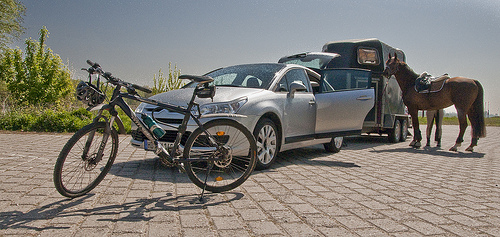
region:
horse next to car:
[380, 51, 487, 153]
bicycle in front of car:
[40, 59, 259, 197]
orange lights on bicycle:
[215, 126, 227, 183]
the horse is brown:
[381, 50, 489, 156]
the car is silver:
[126, 60, 383, 172]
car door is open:
[313, 63, 379, 136]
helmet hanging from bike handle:
[74, 57, 115, 110]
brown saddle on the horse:
[411, 69, 450, 95]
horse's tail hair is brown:
[471, 80, 488, 140]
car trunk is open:
[276, 50, 341, 78]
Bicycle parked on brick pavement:
[37, 57, 257, 199]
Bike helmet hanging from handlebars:
[73, 63, 105, 108]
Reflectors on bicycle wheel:
[210, 127, 227, 185]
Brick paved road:
[4, 124, 496, 235]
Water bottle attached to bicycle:
[138, 107, 164, 140]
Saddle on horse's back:
[412, 72, 449, 91]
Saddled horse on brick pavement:
[383, 51, 487, 155]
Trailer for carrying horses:
[322, 39, 409, 144]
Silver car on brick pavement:
[130, 47, 377, 165]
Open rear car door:
[311, 63, 377, 137]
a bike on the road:
[33, 43, 338, 235]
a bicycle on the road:
[46, 36, 286, 231]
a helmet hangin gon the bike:
[30, 28, 160, 170]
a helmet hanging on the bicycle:
[54, 57, 156, 173]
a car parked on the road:
[158, 6, 424, 228]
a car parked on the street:
[144, 4, 384, 232]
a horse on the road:
[367, 31, 496, 168]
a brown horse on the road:
[326, 29, 499, 213]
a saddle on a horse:
[373, 41, 489, 138]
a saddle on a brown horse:
[368, 26, 495, 157]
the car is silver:
[116, 34, 436, 220]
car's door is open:
[295, 64, 384, 159]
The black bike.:
[50, 58, 270, 215]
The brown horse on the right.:
[385, 46, 495, 158]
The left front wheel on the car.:
[254, 120, 281, 164]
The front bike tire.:
[55, 122, 126, 189]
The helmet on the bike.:
[69, 80, 104, 108]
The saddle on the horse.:
[417, 63, 448, 96]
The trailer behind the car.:
[325, 42, 419, 144]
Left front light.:
[197, 98, 248, 115]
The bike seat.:
[178, 73, 215, 90]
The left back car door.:
[317, 64, 385, 145]